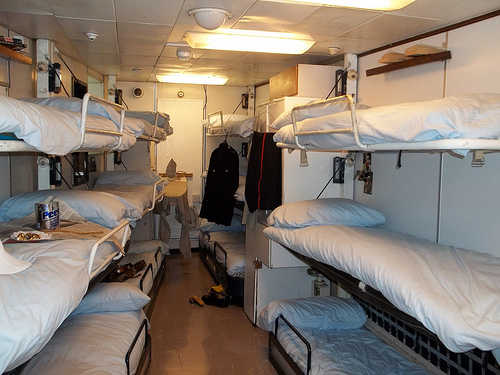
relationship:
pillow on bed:
[43, 96, 92, 110] [308, 97, 428, 159]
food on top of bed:
[10, 225, 54, 244] [308, 97, 428, 159]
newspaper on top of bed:
[58, 204, 91, 221] [308, 97, 428, 159]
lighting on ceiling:
[230, 32, 276, 52] [102, 0, 155, 28]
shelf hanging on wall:
[411, 53, 438, 72] [443, 46, 482, 78]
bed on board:
[308, 97, 428, 159] [25, 131, 87, 158]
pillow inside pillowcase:
[43, 96, 92, 110] [281, 104, 312, 117]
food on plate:
[10, 225, 54, 244] [21, 230, 38, 238]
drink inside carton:
[45, 202, 56, 210] [39, 206, 59, 232]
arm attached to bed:
[303, 95, 358, 117] [308, 97, 428, 159]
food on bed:
[10, 225, 54, 244] [308, 97, 428, 159]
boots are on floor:
[179, 285, 211, 309] [172, 323, 233, 355]